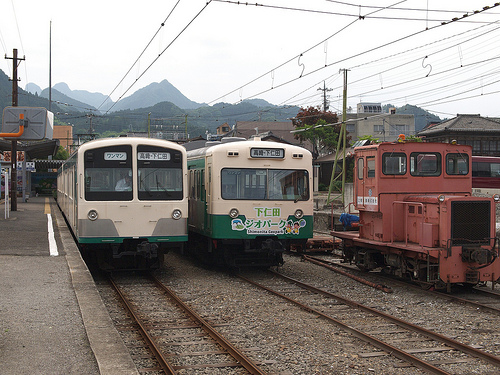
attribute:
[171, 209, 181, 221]
light — off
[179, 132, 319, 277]
rail car — green, cream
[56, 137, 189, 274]
train — white 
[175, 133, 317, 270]
train — motionless, passenger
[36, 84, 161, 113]
mountains — distant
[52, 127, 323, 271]
trains — electric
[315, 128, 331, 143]
leaves — green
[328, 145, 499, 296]
train — motionless, short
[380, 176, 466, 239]
color — white 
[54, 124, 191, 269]
train — motionless, passenger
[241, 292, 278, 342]
stone — small 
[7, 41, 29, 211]
pole — wooden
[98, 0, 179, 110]
wire — electrical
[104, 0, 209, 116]
wire — electrical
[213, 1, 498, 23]
wire — electrical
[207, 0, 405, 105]
wire — electrical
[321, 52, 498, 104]
wire — electrical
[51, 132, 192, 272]
rail car — green, white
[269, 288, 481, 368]
rails — rusty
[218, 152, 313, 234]
train — electric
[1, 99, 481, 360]
train station — rural